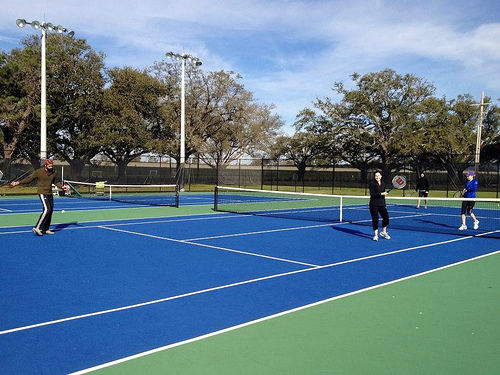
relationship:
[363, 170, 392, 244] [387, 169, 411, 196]
woman holding tennis racket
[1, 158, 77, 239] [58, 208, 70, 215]
man swinging at tennis ball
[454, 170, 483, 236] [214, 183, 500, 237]
person standing near net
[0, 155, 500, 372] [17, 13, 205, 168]
tennis court lighting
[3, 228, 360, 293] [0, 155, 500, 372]
white, blue and green tennis courts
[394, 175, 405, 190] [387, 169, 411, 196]
white and black tennis racket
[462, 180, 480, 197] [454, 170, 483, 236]
blue top on lady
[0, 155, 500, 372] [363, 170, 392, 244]
tennis racket with lady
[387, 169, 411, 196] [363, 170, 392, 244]
tennis racket with lady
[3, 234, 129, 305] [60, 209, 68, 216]
tennis ball in air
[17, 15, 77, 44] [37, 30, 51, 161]
lights on tall silver pole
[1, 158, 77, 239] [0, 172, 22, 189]
man swinging raquet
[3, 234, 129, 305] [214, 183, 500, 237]
blue tennis court net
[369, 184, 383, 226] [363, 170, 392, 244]
black outfit on woman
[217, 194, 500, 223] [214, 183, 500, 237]
white and black tennis net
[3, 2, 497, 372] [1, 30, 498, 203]
park has trees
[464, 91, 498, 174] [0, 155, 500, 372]
telephone pole near courts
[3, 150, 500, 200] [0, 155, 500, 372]
tennis fence behind tennis courts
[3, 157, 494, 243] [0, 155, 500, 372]
four persons playing ten on tennis court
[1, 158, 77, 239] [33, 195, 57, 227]
man wearing white and black tennis pants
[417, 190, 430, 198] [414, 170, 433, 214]
black shorts on man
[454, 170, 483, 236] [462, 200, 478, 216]
woman wearing black capri pants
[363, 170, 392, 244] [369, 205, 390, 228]
woman with black athletic pants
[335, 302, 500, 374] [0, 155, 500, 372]
green and blue tennis court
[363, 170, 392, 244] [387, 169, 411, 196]
woman with a ten racket with w on it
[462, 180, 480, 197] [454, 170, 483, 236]
royal blue pullover on woman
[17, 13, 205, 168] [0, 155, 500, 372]
two light posts on tennis court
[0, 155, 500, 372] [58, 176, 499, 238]
tennis court has two nets stretched across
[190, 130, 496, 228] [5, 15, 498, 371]
net in middle of court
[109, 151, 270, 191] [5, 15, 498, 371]
fence surrounds court